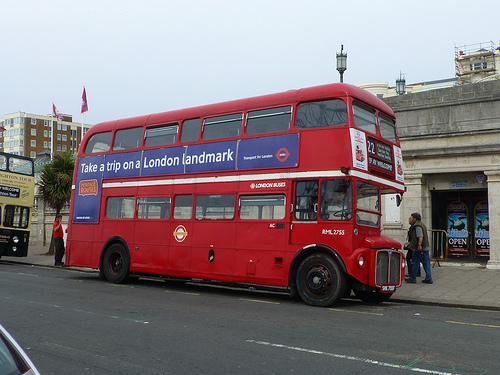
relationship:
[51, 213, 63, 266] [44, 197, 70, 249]
man wears shirt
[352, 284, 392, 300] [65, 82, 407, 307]
front tire of bus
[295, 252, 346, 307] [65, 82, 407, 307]
front tire of bus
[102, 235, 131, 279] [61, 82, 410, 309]
tire of bus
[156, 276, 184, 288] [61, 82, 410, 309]
tire of bus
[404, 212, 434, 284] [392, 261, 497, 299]
man walking on sidewalk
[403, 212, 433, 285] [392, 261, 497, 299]
people walking on sidewalk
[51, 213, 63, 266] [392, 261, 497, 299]
man walking on sidewalk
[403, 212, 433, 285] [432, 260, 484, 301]
people standing on sidewalk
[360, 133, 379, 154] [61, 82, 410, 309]
22 on bus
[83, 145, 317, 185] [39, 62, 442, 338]
sign on bus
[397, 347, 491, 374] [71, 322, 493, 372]
green on road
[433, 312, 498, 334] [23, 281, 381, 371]
yellowline on road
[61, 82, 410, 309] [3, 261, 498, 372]
bus parked on road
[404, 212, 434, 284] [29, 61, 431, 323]
man near a bus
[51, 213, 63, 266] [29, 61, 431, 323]
man near a bus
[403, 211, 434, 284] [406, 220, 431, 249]
man wearing jacket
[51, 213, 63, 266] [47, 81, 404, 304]
man wearing shirt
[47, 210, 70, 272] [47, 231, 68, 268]
man wearing pants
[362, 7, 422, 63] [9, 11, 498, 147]
clouds in sky